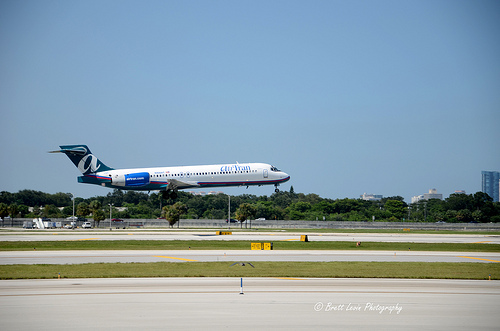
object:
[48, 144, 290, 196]
airplane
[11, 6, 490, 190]
sky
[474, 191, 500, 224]
trees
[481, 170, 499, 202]
skyscraper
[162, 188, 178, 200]
landing gear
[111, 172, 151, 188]
engine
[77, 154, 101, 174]
letter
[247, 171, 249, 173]
windows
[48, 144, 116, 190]
tail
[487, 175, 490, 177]
windows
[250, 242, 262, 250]
squares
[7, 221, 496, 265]
runway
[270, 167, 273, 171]
pilot window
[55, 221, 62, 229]
cars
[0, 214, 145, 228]
parking lot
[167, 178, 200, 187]
wing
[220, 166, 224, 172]
writing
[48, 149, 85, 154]
tail fin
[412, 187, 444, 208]
building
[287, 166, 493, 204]
background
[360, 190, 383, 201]
building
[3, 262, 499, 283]
grass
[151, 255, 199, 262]
yellow stripe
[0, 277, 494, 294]
curb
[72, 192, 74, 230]
pole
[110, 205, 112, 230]
pole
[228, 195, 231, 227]
pole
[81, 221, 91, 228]
car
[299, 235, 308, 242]
block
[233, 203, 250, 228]
tree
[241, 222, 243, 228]
trunk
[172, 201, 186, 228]
tree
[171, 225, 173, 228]
trunk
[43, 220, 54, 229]
car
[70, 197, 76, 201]
lights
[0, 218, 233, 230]
fence